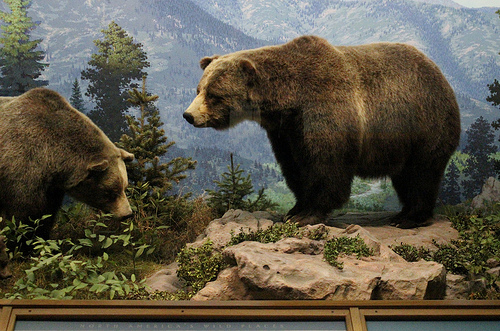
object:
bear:
[182, 35, 461, 229]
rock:
[139, 208, 447, 299]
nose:
[183, 113, 194, 124]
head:
[183, 50, 260, 131]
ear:
[200, 56, 214, 70]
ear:
[240, 58, 257, 75]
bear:
[0, 88, 134, 257]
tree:
[0, 0, 48, 97]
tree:
[70, 78, 85, 113]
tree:
[80, 20, 150, 143]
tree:
[115, 72, 197, 200]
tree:
[460, 117, 499, 199]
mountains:
[1, 0, 500, 205]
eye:
[208, 93, 214, 98]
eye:
[197, 90, 200, 95]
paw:
[286, 209, 334, 226]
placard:
[11, 318, 349, 331]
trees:
[160, 87, 199, 103]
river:
[352, 181, 385, 199]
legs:
[284, 119, 359, 227]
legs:
[389, 143, 456, 230]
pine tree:
[273, 160, 279, 170]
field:
[2, 153, 499, 303]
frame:
[1, 298, 500, 331]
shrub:
[436, 215, 498, 298]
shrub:
[175, 241, 223, 299]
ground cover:
[325, 234, 366, 272]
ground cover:
[223, 222, 327, 248]